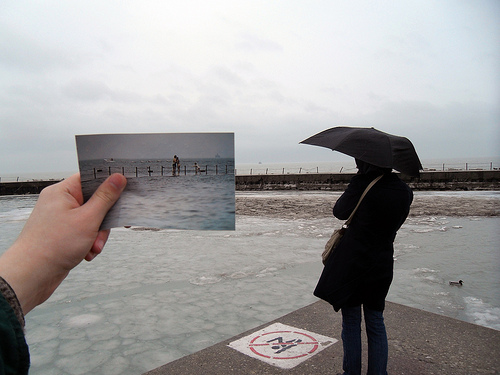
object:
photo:
[70, 130, 237, 234]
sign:
[224, 320, 337, 370]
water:
[0, 184, 499, 375]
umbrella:
[299, 126, 424, 182]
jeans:
[337, 298, 388, 374]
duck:
[446, 279, 464, 288]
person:
[171, 153, 176, 176]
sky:
[0, 1, 497, 178]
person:
[310, 152, 414, 372]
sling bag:
[319, 172, 386, 264]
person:
[1, 170, 128, 374]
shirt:
[309, 170, 416, 311]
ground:
[140, 288, 499, 374]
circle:
[248, 327, 320, 360]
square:
[226, 321, 336, 372]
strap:
[341, 175, 381, 233]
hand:
[9, 169, 129, 273]